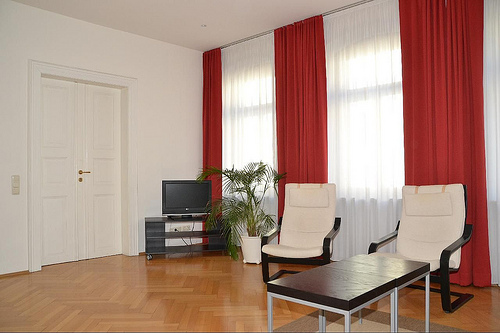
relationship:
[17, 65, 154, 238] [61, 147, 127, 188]
doors with knobs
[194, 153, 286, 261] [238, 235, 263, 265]
palm in planter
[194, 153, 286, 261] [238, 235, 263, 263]
palm inside of planter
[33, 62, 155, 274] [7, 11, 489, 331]
doors leading into room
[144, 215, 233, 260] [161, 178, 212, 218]
cabinet under tv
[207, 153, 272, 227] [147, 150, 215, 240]
palm next to tv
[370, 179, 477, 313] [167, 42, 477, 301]
chair in room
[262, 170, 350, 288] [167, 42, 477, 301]
chair in room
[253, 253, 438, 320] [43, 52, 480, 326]
table in room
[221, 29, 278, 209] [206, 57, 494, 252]
curtains on windows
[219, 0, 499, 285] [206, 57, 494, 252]
curtains on windows